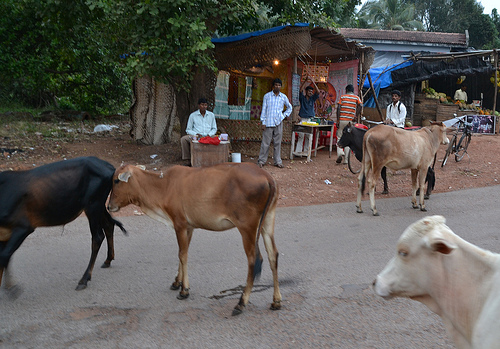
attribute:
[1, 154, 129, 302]
cow — black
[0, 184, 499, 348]
road — paved, gravel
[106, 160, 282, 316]
cow — light brown, adolescent, facing, brown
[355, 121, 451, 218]
cow — tan, beige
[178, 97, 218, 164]
man — sitting, seated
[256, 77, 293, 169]
man — standing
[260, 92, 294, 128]
shirt — blue, white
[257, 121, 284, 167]
pants — grey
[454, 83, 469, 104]
man — selling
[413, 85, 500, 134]
stand — produce stand, outdoor, small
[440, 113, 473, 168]
bicycle — parked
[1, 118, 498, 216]
ground — dirt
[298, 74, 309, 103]
arm — raised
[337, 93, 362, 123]
shirt — orange, striped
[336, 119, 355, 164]
pants — khaki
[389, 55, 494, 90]
tarp — black, fabric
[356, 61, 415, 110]
tarp — blue, plastic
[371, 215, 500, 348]
cow — white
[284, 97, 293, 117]
arm — bent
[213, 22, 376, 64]
roof — blue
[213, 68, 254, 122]
material — blue, white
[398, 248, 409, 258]
eye — staring